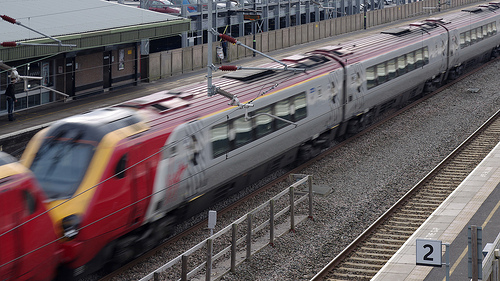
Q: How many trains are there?
A: One.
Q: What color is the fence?
A: Light grey.